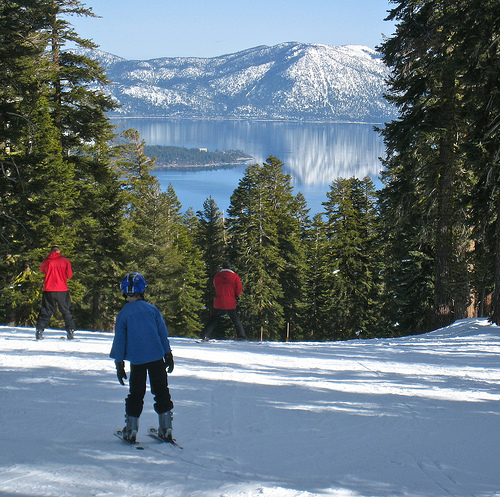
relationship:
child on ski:
[108, 267, 177, 439] [113, 429, 148, 452]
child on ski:
[108, 267, 177, 439] [146, 424, 187, 453]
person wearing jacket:
[34, 242, 78, 341] [38, 252, 72, 294]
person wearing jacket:
[199, 260, 245, 340] [209, 270, 243, 311]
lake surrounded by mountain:
[58, 116, 407, 226] [34, 40, 430, 124]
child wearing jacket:
[108, 267, 177, 439] [109, 300, 172, 365]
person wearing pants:
[34, 242, 78, 341] [36, 288, 74, 334]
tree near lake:
[222, 163, 289, 341] [58, 116, 407, 226]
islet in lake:
[90, 142, 251, 173] [58, 116, 407, 226]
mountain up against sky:
[34, 40, 430, 124] [57, 0, 411, 62]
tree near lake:
[123, 181, 182, 338] [58, 116, 407, 226]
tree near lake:
[325, 177, 380, 338] [58, 116, 407, 226]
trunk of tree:
[256, 324, 268, 342] [222, 163, 289, 341]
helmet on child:
[118, 268, 146, 295] [108, 267, 177, 439]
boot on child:
[119, 411, 141, 444] [108, 267, 177, 439]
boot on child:
[157, 407, 176, 439] [108, 267, 177, 439]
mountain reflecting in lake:
[34, 40, 430, 124] [58, 116, 407, 226]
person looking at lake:
[34, 242, 78, 341] [58, 116, 407, 226]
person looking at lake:
[199, 260, 245, 340] [58, 116, 407, 226]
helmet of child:
[118, 268, 146, 295] [108, 267, 177, 439]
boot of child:
[119, 411, 141, 444] [108, 267, 177, 439]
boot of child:
[157, 407, 176, 439] [108, 267, 177, 439]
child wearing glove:
[108, 267, 177, 439] [115, 360, 128, 389]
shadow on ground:
[4, 347, 244, 374] [1, 316, 499, 495]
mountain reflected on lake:
[34, 40, 430, 124] [58, 116, 407, 226]